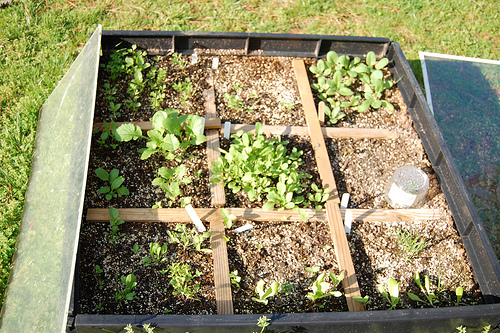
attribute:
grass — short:
[0, 0, 499, 315]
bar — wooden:
[206, 230, 255, 328]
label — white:
[178, 203, 208, 242]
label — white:
[337, 208, 354, 237]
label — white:
[333, 189, 355, 214]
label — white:
[214, 112, 236, 144]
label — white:
[208, 55, 220, 75]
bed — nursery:
[67, 21, 499, 331]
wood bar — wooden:
[193, 52, 238, 315]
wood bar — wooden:
[282, 57, 368, 306]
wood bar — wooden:
[101, 114, 401, 146]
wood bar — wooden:
[90, 202, 453, 226]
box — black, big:
[16, 31, 498, 329]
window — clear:
[415, 50, 499, 246]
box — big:
[77, 26, 499, 332]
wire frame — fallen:
[420, 47, 495, 260]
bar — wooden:
[288, 43, 363, 310]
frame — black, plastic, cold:
[62, 28, 497, 330]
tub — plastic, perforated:
[67, 27, 484, 324]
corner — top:
[305, 37, 415, 133]